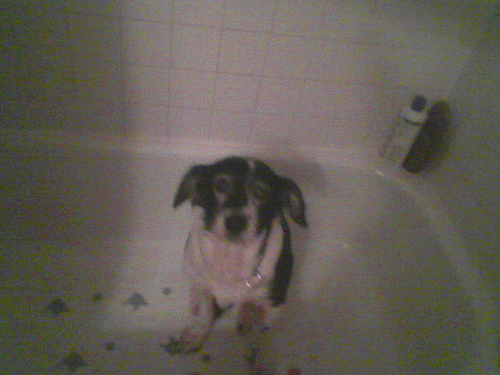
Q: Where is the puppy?
A: In a bathtub.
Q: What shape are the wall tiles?
A: Square.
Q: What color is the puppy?
A: Black and white.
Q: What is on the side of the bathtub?
A: Shampoo.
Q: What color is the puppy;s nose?
A: Black.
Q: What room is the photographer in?
A: The bathroom.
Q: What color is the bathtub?
A: White.